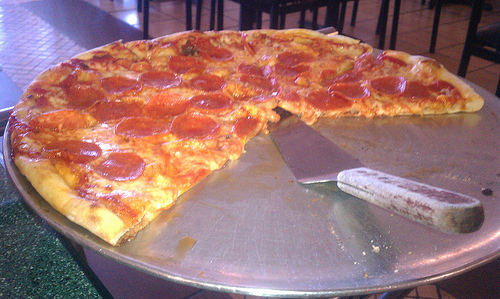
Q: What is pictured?
A: A pepperoni pizza.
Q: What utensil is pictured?
A: A spatula.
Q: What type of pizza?
A: Pepperoni.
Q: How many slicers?
A: One.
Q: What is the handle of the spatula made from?
A: Wood.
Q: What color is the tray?
A: Silver.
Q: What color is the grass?
A: Green.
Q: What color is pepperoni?
A: Red.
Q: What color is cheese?
A: Yellow.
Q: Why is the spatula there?
A: To cut pizza.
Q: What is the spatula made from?
A: SIlver.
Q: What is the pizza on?
A: Pan.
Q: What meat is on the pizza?
A: Pepperoni.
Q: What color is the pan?
A: Silver.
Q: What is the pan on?
A: Table.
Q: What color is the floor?
A: Brown.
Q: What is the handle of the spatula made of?
A: Wood.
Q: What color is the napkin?
A: Green.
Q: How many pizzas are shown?
A: 1.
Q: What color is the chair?
A: Black.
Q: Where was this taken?
A: Restaurant.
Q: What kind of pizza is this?
A: Pepperoni.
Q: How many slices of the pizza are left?
A: 5.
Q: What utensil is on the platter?
A: Pizza server.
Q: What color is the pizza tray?
A: Silver.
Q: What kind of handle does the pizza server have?
A: Wood.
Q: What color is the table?
A: Green.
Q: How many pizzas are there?
A: 1.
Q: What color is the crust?
A: Brown.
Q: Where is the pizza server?
A: On the tray.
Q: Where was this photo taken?
A: At a restaurant.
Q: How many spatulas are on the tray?
A: One.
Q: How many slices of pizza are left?
A: Five.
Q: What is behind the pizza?
A: Chairs.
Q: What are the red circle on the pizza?
A: Pepperoni.